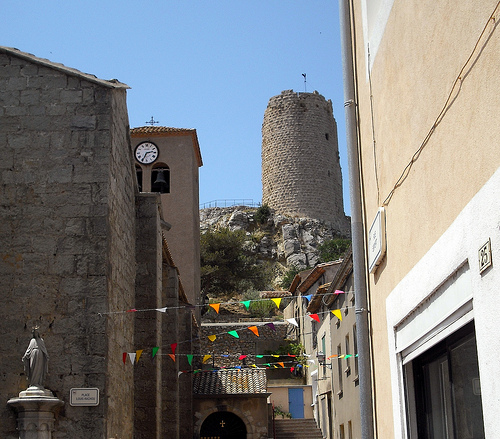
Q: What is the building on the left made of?
A: Bricks.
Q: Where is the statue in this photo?
A: Bottom left.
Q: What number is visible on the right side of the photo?
A: 25.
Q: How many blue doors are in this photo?
A: One.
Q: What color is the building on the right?
A: Tan and white.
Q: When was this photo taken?
A: During the day.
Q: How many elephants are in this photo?
A: Zero.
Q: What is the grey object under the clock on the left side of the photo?
A: Bell.